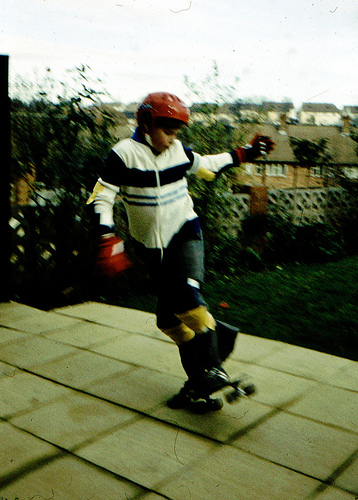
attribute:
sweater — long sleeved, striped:
[85, 126, 243, 258]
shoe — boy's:
[204, 351, 239, 382]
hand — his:
[221, 133, 286, 165]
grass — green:
[99, 245, 356, 359]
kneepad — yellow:
[176, 305, 217, 333]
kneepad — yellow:
[162, 321, 195, 341]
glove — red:
[93, 233, 131, 272]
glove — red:
[236, 131, 273, 165]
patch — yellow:
[195, 166, 228, 178]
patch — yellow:
[86, 179, 104, 206]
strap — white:
[141, 134, 152, 145]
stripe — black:
[104, 156, 196, 186]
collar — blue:
[126, 125, 143, 138]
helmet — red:
[132, 90, 190, 126]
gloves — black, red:
[230, 129, 278, 164]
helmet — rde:
[132, 89, 190, 153]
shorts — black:
[140, 243, 208, 315]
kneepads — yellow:
[143, 268, 218, 318]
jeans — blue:
[154, 220, 205, 314]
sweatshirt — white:
[82, 134, 235, 260]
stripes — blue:
[115, 180, 188, 212]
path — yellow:
[227, 236, 345, 346]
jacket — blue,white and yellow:
[91, 124, 238, 234]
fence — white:
[217, 187, 355, 230]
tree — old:
[15, 107, 120, 271]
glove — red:
[228, 134, 271, 163]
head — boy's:
[138, 91, 187, 152]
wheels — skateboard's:
[194, 384, 257, 417]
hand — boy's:
[102, 234, 127, 270]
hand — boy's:
[238, 136, 274, 158]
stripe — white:
[215, 371, 229, 382]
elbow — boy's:
[192, 164, 222, 181]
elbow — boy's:
[88, 177, 102, 212]